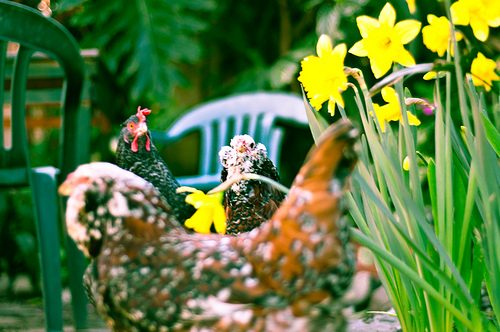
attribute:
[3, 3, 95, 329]
chair — plastic, green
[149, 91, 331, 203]
chair — plastic, green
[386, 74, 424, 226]
stem — green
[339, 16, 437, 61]
flower — yellow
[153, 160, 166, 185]
feathers — black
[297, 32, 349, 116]
bloom — buttercup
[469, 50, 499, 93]
bloom — buttercup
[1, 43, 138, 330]
table — green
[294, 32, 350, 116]
flower — bloomed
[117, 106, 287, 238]
rooster — black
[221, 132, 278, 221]
rooster — NEXT TO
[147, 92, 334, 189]
chair — white 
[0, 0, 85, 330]
chair — green, plastic, BY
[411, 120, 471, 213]
leaf — green